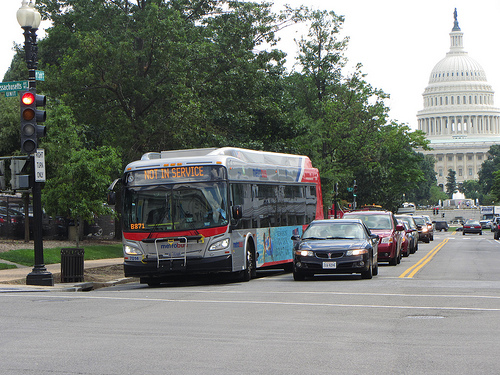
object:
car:
[291, 219, 379, 281]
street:
[233, 317, 337, 371]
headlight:
[294, 249, 368, 257]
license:
[322, 261, 336, 269]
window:
[301, 223, 368, 239]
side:
[370, 234, 380, 244]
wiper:
[301, 236, 359, 240]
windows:
[230, 181, 317, 229]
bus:
[106, 147, 324, 288]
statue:
[451, 8, 461, 32]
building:
[411, 8, 499, 208]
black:
[34, 148, 46, 182]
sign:
[34, 148, 47, 182]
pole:
[18, 25, 54, 287]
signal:
[19, 92, 37, 154]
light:
[22, 92, 35, 105]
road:
[217, 304, 500, 375]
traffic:
[276, 202, 500, 298]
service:
[171, 166, 203, 178]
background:
[370, 5, 431, 46]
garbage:
[59, 248, 85, 283]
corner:
[53, 282, 100, 291]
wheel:
[241, 236, 253, 281]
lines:
[398, 237, 450, 278]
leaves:
[167, 56, 235, 98]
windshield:
[120, 165, 230, 233]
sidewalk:
[86, 258, 123, 268]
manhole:
[406, 314, 447, 318]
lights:
[22, 92, 36, 152]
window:
[121, 166, 230, 233]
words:
[144, 166, 203, 180]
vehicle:
[342, 210, 405, 266]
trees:
[275, 9, 390, 219]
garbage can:
[60, 248, 85, 283]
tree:
[9, 0, 232, 241]